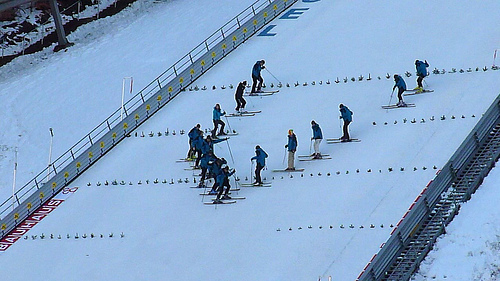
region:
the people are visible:
[164, 91, 266, 235]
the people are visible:
[188, 94, 298, 269]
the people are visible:
[207, 134, 274, 239]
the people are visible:
[187, 106, 247, 205]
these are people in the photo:
[186, 57, 276, 191]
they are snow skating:
[185, 52, 294, 199]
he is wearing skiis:
[228, 189, 245, 204]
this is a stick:
[268, 67, 278, 79]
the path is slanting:
[271, 180, 373, 279]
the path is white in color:
[168, 218, 233, 278]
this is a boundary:
[85, 111, 122, 152]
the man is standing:
[281, 124, 301, 169]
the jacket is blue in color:
[257, 150, 265, 162]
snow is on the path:
[88, 10, 126, 37]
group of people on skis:
[165, 43, 452, 214]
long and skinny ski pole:
[266, 69, 283, 84]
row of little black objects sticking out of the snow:
[264, 220, 395, 233]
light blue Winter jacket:
[333, 107, 361, 123]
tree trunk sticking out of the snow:
[45, 5, 80, 60]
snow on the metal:
[438, 180, 460, 207]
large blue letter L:
[255, 17, 282, 39]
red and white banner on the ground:
[0, 175, 82, 250]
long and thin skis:
[298, 152, 329, 159]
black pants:
[341, 120, 352, 142]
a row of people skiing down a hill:
[182, 120, 237, 212]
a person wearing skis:
[306, 120, 328, 169]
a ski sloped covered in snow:
[113, 17, 458, 266]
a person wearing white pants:
[281, 122, 303, 174]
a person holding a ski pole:
[383, 70, 408, 109]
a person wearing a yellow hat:
[271, 123, 300, 176]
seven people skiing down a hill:
[246, 59, 438, 183]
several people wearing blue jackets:
[177, 113, 236, 201]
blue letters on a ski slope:
[253, 2, 317, 52]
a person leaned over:
[248, 57, 274, 90]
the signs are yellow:
[47, 185, 72, 196]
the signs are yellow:
[67, 175, 88, 202]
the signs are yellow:
[59, 166, 79, 202]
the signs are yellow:
[60, 169, 64, 179]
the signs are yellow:
[56, 177, 81, 185]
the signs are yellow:
[61, 168, 101, 213]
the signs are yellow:
[77, 159, 83, 176]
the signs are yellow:
[73, 153, 81, 170]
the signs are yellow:
[74, 160, 114, 202]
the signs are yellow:
[75, 160, 109, 182]